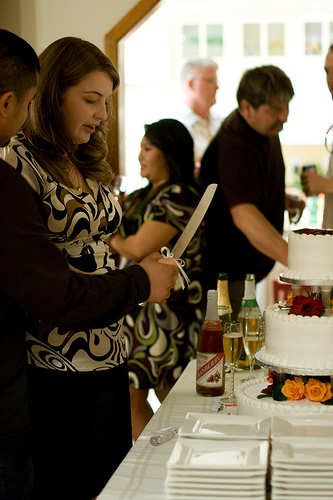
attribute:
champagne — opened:
[209, 264, 265, 369]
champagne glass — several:
[220, 317, 243, 405]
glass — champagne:
[225, 322, 241, 364]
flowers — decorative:
[262, 369, 331, 407]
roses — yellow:
[278, 375, 332, 404]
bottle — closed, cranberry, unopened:
[193, 286, 228, 398]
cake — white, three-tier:
[227, 223, 331, 456]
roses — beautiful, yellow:
[273, 372, 331, 404]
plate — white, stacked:
[177, 408, 271, 441]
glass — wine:
[188, 267, 238, 410]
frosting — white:
[271, 313, 306, 320]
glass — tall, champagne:
[220, 318, 242, 405]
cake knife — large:
[138, 179, 218, 309]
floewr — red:
[283, 285, 319, 314]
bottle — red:
[191, 285, 233, 402]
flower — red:
[287, 293, 324, 318]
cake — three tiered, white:
[278, 227, 328, 286]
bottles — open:
[196, 261, 280, 381]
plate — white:
[161, 375, 293, 476]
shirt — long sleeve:
[1, 149, 148, 397]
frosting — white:
[267, 307, 329, 335]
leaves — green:
[256, 383, 286, 399]